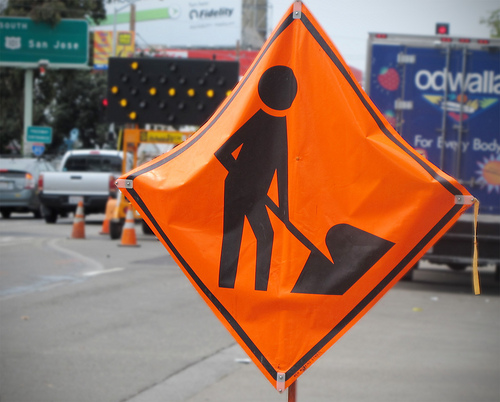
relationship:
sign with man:
[118, 1, 477, 398] [211, 62, 308, 293]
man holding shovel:
[211, 62, 308, 293] [268, 199, 390, 300]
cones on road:
[68, 192, 161, 249] [3, 211, 500, 399]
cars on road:
[38, 148, 124, 222] [3, 211, 500, 399]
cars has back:
[38, 148, 124, 222] [38, 167, 116, 204]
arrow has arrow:
[111, 61, 232, 118] [111, 61, 232, 118]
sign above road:
[2, 16, 89, 68] [3, 211, 500, 399]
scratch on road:
[116, 343, 261, 397] [3, 211, 500, 399]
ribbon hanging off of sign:
[468, 195, 486, 295] [118, 1, 477, 398]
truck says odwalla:
[365, 25, 499, 289] [413, 69, 499, 102]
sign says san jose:
[2, 16, 89, 68] [28, 38, 80, 52]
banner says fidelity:
[91, 3, 272, 47] [187, 7, 241, 22]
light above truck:
[434, 23, 452, 33] [365, 25, 499, 289]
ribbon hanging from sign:
[468, 195, 486, 295] [118, 1, 477, 398]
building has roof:
[132, 38, 383, 181] [150, 48, 254, 78]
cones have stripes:
[68, 192, 161, 249] [69, 202, 137, 227]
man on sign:
[211, 62, 308, 293] [118, 1, 477, 398]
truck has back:
[365, 25, 499, 289] [371, 44, 498, 213]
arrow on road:
[111, 61, 232, 118] [3, 211, 500, 399]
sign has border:
[118, 1, 477, 398] [128, 15, 465, 378]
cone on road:
[118, 201, 142, 245] [3, 211, 500, 399]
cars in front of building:
[2, 139, 132, 226] [132, 38, 383, 181]